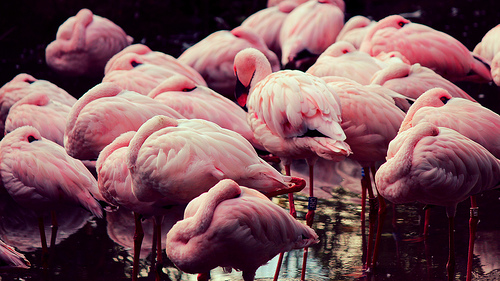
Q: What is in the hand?
A: Flamingo.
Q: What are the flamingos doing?
A: Resting.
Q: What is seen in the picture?
A: Flamingos.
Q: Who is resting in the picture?
A: The pink flamingo.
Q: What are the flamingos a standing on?
A: The ground.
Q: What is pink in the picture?
A: The flamingos.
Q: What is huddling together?
A: The pink flamingos.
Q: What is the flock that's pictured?
A: Pink flamingo.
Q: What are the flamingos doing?
A: Sleeping.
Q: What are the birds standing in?
A: Water.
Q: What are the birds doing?
A: Standing and sleeping.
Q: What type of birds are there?
A: Pink flamingos.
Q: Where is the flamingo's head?
A: Tucked in.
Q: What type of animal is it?
A: Pink flamingos.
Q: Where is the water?
A: By the flamingo's feet.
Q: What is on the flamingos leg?
A: A tag.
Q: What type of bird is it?
A: Flamingo.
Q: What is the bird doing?
A: Standing on both legs.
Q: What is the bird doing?
A: Standing.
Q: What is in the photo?
A: Birds.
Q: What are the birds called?
A: Flamingos.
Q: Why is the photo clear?
A: Its during the day.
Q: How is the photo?
A: Clear.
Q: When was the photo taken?
A: Daytime.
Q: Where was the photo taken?
A: At a lake.